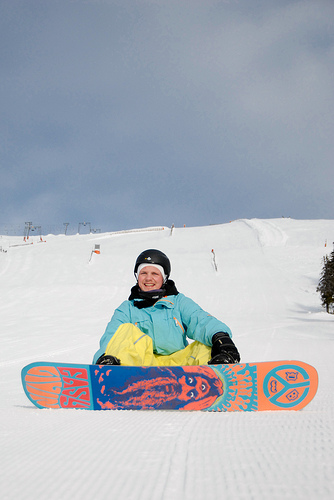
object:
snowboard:
[20, 362, 319, 412]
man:
[92, 246, 241, 363]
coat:
[93, 293, 236, 367]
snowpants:
[107, 322, 213, 365]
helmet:
[134, 248, 169, 280]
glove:
[209, 333, 240, 365]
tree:
[316, 248, 334, 311]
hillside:
[0, 212, 333, 500]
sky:
[1, 2, 333, 235]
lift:
[2, 218, 103, 240]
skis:
[9, 242, 33, 247]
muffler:
[128, 281, 179, 309]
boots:
[96, 352, 121, 366]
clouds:
[5, 14, 334, 216]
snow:
[13, 245, 323, 496]